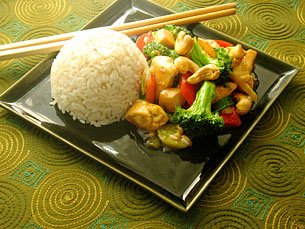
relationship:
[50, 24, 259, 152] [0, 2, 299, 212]
meal on top of plate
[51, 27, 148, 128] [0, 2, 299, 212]
rice on top of plate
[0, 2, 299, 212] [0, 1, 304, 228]
plate on top of cloth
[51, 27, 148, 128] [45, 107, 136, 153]
rice has shadow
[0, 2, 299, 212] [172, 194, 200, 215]
plate has corner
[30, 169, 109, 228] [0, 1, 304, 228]
shapes on top of cloth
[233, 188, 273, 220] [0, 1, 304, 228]
lines on top of cloth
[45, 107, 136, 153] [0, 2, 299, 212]
shadow on top of plate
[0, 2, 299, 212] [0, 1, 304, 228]
plate sits on cloth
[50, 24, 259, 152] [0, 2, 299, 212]
meal sits on plate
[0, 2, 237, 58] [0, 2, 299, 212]
chop stick on top of plate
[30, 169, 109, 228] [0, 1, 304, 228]
shapes on top of table